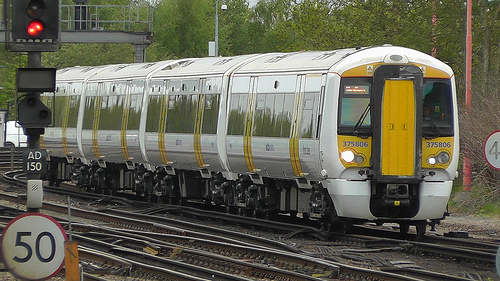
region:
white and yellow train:
[32, 46, 459, 216]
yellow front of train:
[337, 80, 462, 179]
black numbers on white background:
[7, 230, 57, 260]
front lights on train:
[337, 145, 445, 170]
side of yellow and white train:
[52, 62, 324, 177]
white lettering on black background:
[10, 150, 48, 172]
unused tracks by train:
[2, 165, 341, 280]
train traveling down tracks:
[11, 43, 471, 219]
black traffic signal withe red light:
[7, 0, 57, 45]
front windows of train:
[340, 77, 450, 126]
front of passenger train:
[345, 74, 458, 233]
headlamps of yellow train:
[333, 139, 375, 186]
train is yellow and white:
[233, 50, 407, 254]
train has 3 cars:
[68, 65, 326, 224]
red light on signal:
[10, 11, 69, 36]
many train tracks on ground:
[80, 207, 217, 277]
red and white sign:
[11, 233, 53, 275]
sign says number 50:
[8, 220, 59, 275]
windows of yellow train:
[225, 97, 315, 142]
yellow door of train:
[377, 77, 424, 187]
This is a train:
[50, 45, 387, 240]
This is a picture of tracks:
[110, 221, 187, 278]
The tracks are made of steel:
[158, 216, 291, 276]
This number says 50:
[4, 215, 109, 251]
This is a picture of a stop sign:
[17, 23, 52, 48]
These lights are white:
[316, 150, 496, 160]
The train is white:
[173, 68, 385, 199]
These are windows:
[226, 90, 351, 149]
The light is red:
[25, 19, 71, 86]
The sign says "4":
[482, 138, 497, 161]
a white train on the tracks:
[40, 41, 457, 232]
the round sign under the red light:
[0, 210, 66, 275]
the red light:
[20, 15, 46, 40]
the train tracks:
[0, 165, 496, 275]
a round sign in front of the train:
[485, 127, 496, 167]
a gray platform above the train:
[0, 0, 155, 45]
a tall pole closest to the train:
[460, 0, 470, 187]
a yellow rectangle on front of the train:
[381, 77, 411, 172]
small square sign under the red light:
[25, 146, 45, 176]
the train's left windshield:
[343, 96, 369, 123]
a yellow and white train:
[37, 42, 460, 235]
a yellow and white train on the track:
[0, 148, 499, 279]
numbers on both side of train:
[336, 136, 452, 147]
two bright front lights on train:
[337, 146, 437, 166]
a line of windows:
[51, 89, 323, 139]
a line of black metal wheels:
[26, 160, 428, 234]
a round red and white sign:
[0, 210, 70, 278]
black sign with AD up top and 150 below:
[21, 145, 48, 176]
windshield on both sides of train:
[337, 75, 455, 139]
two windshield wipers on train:
[352, 100, 444, 130]